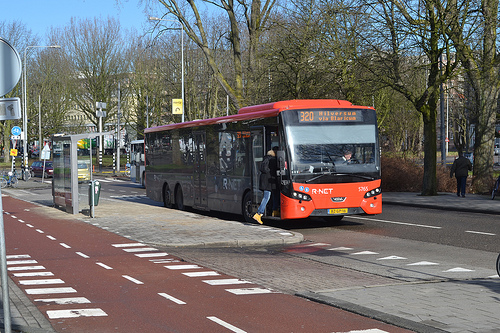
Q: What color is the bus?
A: Orange and black.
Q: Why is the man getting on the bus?
A: To ride it.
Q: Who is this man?
A: A passenger.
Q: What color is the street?
A: Black and red.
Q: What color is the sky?
A: Blue.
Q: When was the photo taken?
A: Daylight hours.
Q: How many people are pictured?
A: 2.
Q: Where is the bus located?
A: On the street.